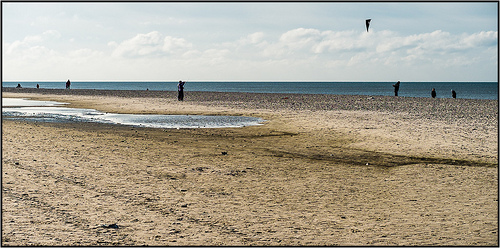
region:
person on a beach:
[388, 79, 403, 95]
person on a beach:
[430, 85, 438, 98]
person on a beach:
[175, 78, 192, 102]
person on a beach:
[63, 77, 73, 91]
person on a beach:
[33, 80, 41, 90]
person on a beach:
[15, 82, 25, 89]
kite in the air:
[362, 16, 375, 38]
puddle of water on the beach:
[1, 92, 260, 137]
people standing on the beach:
[14, 70, 461, 101]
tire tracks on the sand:
[8, 153, 260, 243]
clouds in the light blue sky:
[12, 19, 499, 74]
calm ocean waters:
[6, 77, 498, 97]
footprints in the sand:
[6, 97, 454, 243]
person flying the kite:
[392, 79, 401, 99]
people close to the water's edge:
[423, 78, 463, 99]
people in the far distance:
[11, 75, 44, 93]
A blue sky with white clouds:
[0, 0, 496, 80]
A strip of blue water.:
[0, 77, 495, 97]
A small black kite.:
[365, 18, 372, 33]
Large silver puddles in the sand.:
[0, 95, 269, 129]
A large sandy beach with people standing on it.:
[2, 87, 494, 245]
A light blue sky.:
[1, 0, 496, 80]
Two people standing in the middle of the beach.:
[177, 79, 186, 99]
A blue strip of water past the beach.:
[0, 80, 495, 95]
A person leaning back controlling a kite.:
[390, 78, 400, 96]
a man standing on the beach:
[171, 78, 190, 103]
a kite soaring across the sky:
[347, 6, 392, 40]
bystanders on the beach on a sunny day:
[377, 71, 468, 106]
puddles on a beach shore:
[1, 88, 290, 153]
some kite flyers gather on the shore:
[359, 11, 471, 106]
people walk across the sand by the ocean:
[6, 73, 96, 98]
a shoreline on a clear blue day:
[2, 78, 498, 107]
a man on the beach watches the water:
[169, 77, 196, 104]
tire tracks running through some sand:
[8, 150, 252, 242]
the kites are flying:
[21, 5, 498, 193]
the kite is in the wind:
[331, 1, 388, 58]